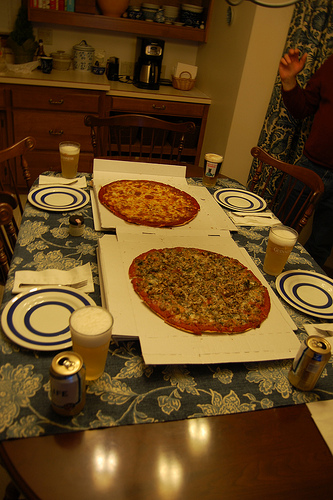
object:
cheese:
[150, 200, 169, 212]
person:
[274, 45, 331, 274]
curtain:
[243, 2, 330, 221]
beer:
[263, 223, 299, 275]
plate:
[275, 267, 333, 320]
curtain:
[270, 62, 303, 185]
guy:
[277, 48, 333, 265]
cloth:
[133, 369, 210, 411]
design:
[205, 161, 217, 178]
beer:
[58, 140, 80, 180]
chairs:
[0, 113, 324, 278]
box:
[115, 227, 302, 365]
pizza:
[98, 179, 198, 228]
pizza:
[129, 247, 271, 334]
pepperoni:
[133, 190, 141, 195]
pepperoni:
[145, 194, 154, 199]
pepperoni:
[134, 185, 143, 188]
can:
[49, 350, 87, 419]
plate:
[27, 184, 90, 212]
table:
[3, 168, 332, 498]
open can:
[50, 350, 87, 417]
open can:
[289, 335, 331, 392]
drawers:
[16, 84, 102, 175]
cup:
[263, 222, 301, 276]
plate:
[214, 187, 267, 213]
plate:
[0, 282, 99, 351]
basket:
[171, 71, 196, 91]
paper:
[174, 62, 198, 79]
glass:
[202, 152, 224, 188]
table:
[35, 172, 326, 498]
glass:
[69, 305, 114, 381]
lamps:
[90, 417, 214, 500]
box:
[89, 171, 239, 232]